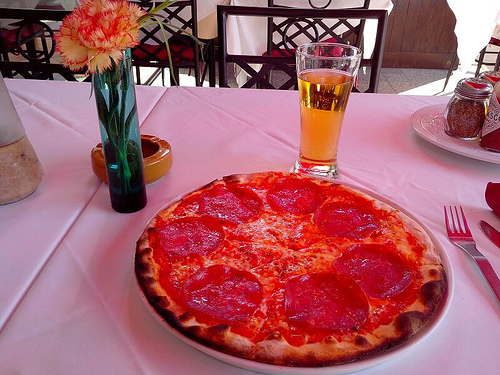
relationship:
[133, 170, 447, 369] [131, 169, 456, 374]
pizza on plate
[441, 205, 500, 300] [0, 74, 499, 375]
fork on table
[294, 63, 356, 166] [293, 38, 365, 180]
beer in glass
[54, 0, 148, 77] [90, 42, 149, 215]
flowers in vase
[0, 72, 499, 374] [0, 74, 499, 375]
tablecloth on table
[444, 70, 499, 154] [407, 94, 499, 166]
spices on plate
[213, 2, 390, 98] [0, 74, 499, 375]
chair by table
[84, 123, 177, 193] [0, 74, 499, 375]
ashtray on table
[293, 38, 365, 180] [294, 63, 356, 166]
glass of beer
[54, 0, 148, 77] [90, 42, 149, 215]
flower in vase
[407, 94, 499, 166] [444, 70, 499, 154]
plate of seasoning containers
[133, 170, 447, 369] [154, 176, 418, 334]
pizza has pepperoni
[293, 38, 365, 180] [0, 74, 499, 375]
glass on table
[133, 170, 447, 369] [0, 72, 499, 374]
food on tablecloth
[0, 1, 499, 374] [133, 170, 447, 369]
restaurant serving pizza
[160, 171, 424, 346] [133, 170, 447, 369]
cheese on pizza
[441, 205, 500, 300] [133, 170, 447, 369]
fork beside pie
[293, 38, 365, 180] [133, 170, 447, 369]
glass next to pie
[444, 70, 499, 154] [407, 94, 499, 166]
condiments on plate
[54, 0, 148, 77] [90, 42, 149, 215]
flowers in container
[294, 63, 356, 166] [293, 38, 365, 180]
drink in glass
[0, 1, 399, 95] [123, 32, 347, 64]
chairs have cushions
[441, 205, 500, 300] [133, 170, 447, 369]
fork next to pizza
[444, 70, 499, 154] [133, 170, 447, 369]
spices near pizza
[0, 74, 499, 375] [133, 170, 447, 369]
table holds food